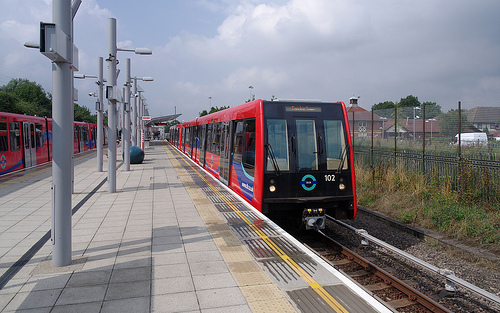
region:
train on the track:
[173, 95, 358, 211]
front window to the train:
[270, 118, 349, 173]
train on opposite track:
[3, 97, 108, 160]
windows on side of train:
[184, 128, 224, 148]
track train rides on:
[308, 228, 420, 303]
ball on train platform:
[126, 143, 148, 166]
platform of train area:
[21, 151, 183, 306]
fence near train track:
[363, 140, 497, 195]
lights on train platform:
[134, 36, 154, 87]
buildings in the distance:
[349, 93, 495, 138]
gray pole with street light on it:
[106, 16, 155, 191]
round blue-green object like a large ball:
[121, 146, 144, 165]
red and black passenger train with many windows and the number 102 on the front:
[167, 100, 359, 230]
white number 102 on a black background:
[322, 172, 338, 184]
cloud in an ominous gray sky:
[164, 12, 370, 67]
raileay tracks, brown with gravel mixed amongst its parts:
[288, 225, 451, 309]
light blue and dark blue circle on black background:
[298, 173, 318, 191]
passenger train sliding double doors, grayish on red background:
[19, 121, 39, 171]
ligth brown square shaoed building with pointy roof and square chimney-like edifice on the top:
[342, 96, 383, 138]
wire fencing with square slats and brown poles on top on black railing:
[353, 107, 498, 198]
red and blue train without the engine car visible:
[1, 110, 122, 179]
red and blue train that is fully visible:
[166, 99, 358, 234]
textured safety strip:
[163, 138, 380, 311]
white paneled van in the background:
[448, 130, 488, 146]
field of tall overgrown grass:
[350, 132, 498, 199]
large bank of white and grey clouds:
[0, 0, 499, 124]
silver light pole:
[104, 14, 154, 192]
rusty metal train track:
[282, 228, 455, 311]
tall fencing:
[346, 101, 499, 204]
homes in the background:
[342, 94, 499, 139]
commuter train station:
[21, 5, 451, 302]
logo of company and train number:
[295, 167, 335, 192]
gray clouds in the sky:
[295, 0, 495, 76]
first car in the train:
[261, 99, 352, 218]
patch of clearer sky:
[140, 2, 227, 47]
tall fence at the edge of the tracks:
[380, 96, 495, 186]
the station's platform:
[80, 151, 200, 303]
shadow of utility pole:
[85, 216, 230, 261]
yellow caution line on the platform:
[235, 215, 266, 242]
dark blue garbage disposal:
[120, 142, 147, 165]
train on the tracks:
[163, 89, 373, 233]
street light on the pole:
[120, 38, 157, 63]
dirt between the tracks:
[345, 232, 382, 259]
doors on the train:
[19, 118, 41, 173]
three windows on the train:
[265, 118, 348, 176]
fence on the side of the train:
[361, 114, 496, 178]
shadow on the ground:
[121, 212, 225, 260]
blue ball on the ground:
[128, 141, 148, 166]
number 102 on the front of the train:
[320, 173, 337, 186]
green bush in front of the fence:
[455, 158, 498, 213]